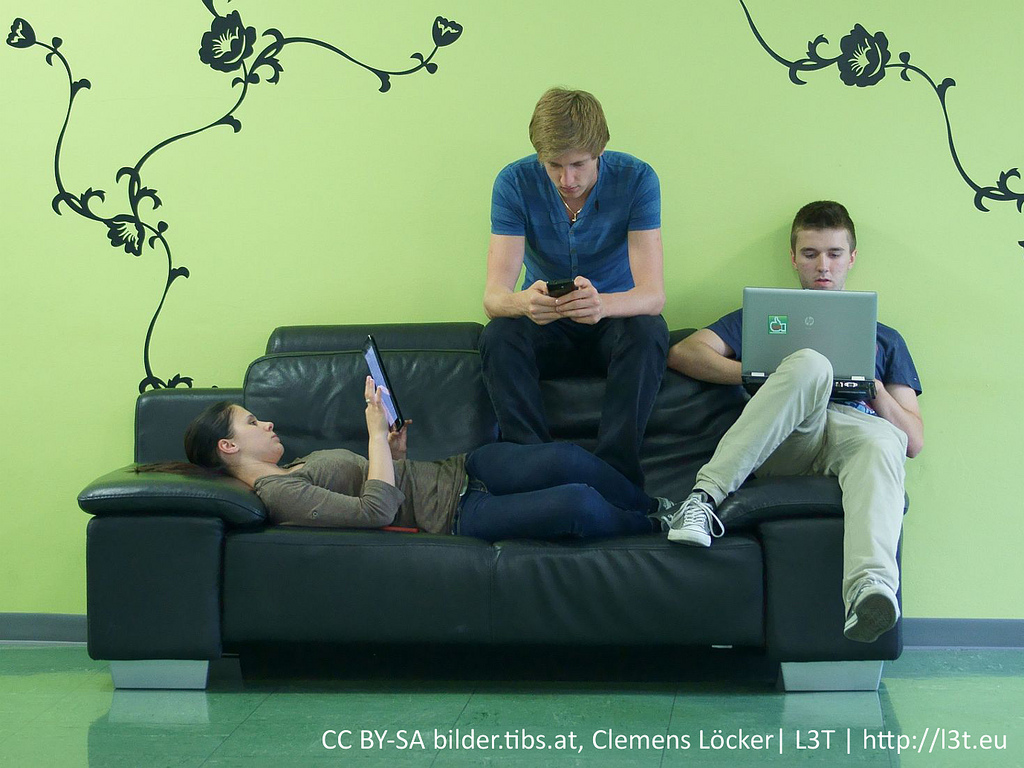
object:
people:
[128, 375, 684, 540]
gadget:
[740, 286, 875, 402]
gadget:
[547, 278, 575, 298]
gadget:
[361, 334, 405, 433]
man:
[666, 200, 923, 643]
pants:
[692, 347, 909, 620]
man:
[477, 86, 671, 490]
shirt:
[492, 150, 662, 292]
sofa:
[77, 321, 909, 690]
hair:
[529, 85, 609, 162]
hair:
[789, 201, 855, 257]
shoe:
[666, 492, 724, 548]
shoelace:
[670, 497, 727, 537]